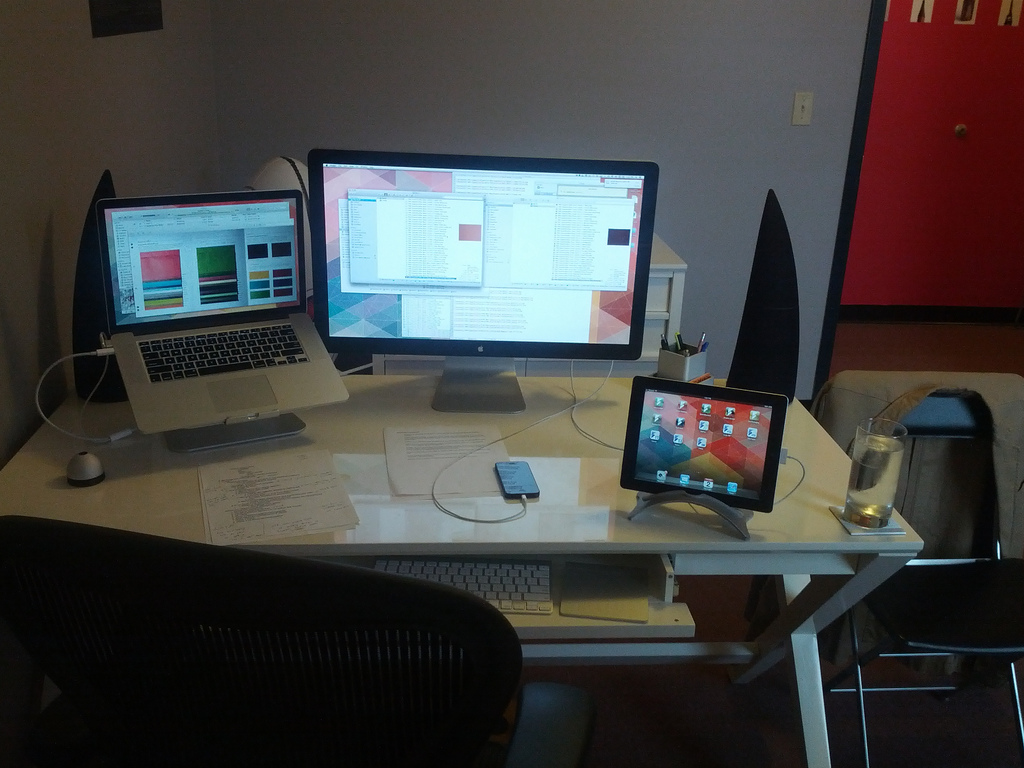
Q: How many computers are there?
A: Two.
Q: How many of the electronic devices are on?
A: All of them.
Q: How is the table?
A: Cluttered.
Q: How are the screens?
A: On.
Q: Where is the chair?
A: Next to the desk.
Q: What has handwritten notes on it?
A: A piece of paper.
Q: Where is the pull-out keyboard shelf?
A: In the desk.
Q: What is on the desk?
A: A pencil holder.